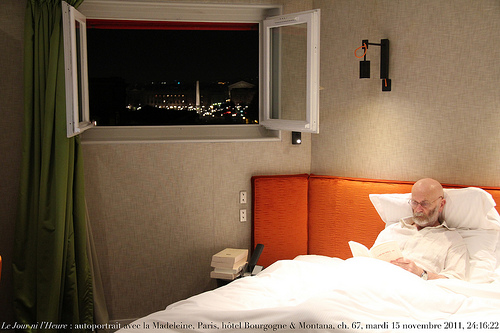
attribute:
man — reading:
[374, 177, 468, 278]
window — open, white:
[63, 0, 322, 140]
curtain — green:
[15, 0, 108, 330]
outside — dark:
[87, 29, 257, 123]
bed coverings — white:
[117, 256, 497, 329]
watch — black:
[421, 269, 430, 278]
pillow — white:
[368, 186, 499, 228]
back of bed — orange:
[253, 173, 499, 267]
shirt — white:
[374, 220, 467, 273]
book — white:
[345, 240, 396, 263]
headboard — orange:
[251, 172, 499, 276]